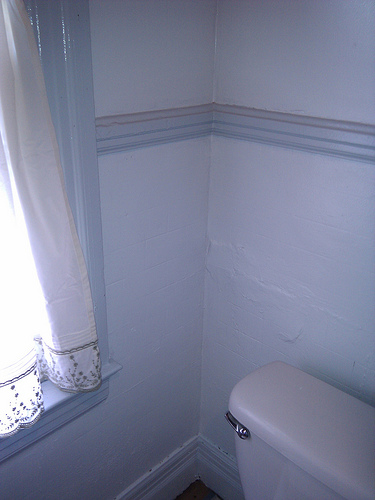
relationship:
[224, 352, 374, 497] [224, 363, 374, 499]
top on tank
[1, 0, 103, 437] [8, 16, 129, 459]
curtain on window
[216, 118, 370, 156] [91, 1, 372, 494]
line on wall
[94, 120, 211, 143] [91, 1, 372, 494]
line on wall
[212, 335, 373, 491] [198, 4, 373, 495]
tank by wall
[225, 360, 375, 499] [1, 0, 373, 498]
tank in bathroom